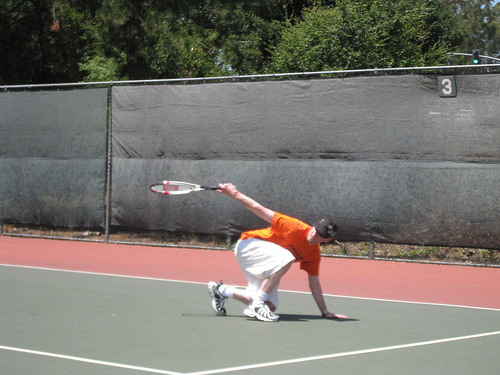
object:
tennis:
[150, 180, 231, 195]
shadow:
[276, 312, 359, 324]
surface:
[6, 222, 499, 368]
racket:
[150, 180, 235, 196]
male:
[206, 182, 347, 323]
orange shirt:
[240, 212, 321, 278]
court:
[0, 230, 498, 374]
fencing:
[1, 69, 493, 249]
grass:
[382, 246, 408, 263]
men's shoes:
[205, 281, 228, 317]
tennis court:
[20, 57, 498, 339]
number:
[440, 79, 453, 97]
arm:
[308, 261, 329, 313]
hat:
[314, 219, 339, 239]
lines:
[20, 333, 471, 368]